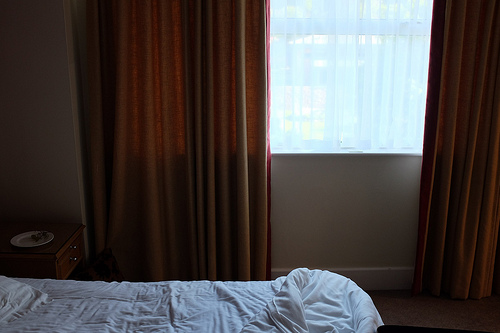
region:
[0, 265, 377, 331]
this is a bed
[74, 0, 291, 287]
this is a curtain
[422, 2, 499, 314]
this is a curtain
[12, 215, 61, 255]
this is a plate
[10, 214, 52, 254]
this is a white plate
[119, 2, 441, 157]
this is a window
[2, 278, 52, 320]
this is a pillow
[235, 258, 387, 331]
this is a white sheet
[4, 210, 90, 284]
this is a bed side table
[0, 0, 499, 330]
this is a bed room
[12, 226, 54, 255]
a plate on a stand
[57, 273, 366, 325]
a white blanket on a bed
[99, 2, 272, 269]
brown cutains at a window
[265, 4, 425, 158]
white shears on a window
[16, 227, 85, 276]
a wooden end stand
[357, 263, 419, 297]
a white base board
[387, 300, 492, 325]
a brown carpet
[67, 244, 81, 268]
knobs on a drawer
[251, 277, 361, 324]
a wrinkled blanket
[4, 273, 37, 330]
a white pillow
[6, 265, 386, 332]
Bed with wrinkled white sheets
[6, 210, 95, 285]
Brown side table with white plate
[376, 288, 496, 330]
Beige short weave carpet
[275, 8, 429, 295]
Sheer drapes and white wall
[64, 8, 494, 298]
Two heavy brown curtains and one light white one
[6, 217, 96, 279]
Brown wood table with silver knobs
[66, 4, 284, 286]
Brown window length curtain with red edge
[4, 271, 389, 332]
White pillow, sheet and blanket on bed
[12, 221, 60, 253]
Round white plate with uneaten food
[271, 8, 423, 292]
Light shinning through white sheer curtain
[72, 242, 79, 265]
silver knobs on night stand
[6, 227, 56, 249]
white plate on night stand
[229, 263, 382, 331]
folded-over top sheet on end of bed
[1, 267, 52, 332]
pillow on bed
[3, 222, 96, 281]
night stand beside bed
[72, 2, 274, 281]
leftmost orange curtain panel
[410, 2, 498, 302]
rightmost orange curtain panel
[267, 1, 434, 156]
white sheer curtains on window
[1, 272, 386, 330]
edge of bed in room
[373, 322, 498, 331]
top edge of chair in room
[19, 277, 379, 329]
unmade bed in the room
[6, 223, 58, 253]
white plate on the nightstand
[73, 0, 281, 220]
curtains hanging in the window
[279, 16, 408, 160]
sheers hanging in the window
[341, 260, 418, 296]
white base board at bottom of wall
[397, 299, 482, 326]
carpet on the floor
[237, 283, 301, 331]
sheet pushed to the end of the bed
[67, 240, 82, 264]
handles on the nightstand drawer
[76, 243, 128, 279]
pillow laying against the curtains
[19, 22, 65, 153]
wall beside the curtains